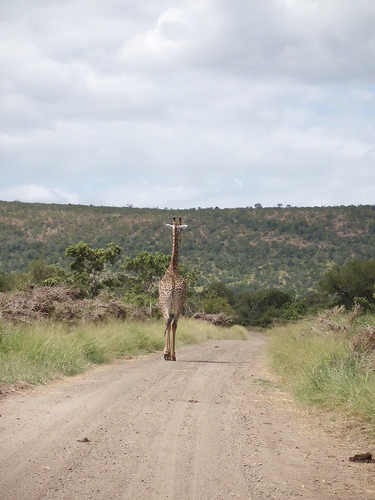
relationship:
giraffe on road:
[155, 217, 186, 361] [1, 325, 373, 496]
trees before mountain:
[0, 240, 374, 331] [1, 201, 374, 299]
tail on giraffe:
[163, 279, 176, 337] [155, 217, 186, 361]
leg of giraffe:
[170, 314, 180, 362] [155, 217, 186, 361]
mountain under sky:
[1, 201, 374, 299] [1, 1, 373, 209]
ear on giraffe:
[178, 222, 189, 230] [155, 217, 186, 361]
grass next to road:
[2, 317, 249, 397] [1, 325, 373, 496]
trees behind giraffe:
[64, 240, 121, 302] [155, 217, 186, 361]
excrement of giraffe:
[77, 434, 90, 444] [155, 217, 186, 361]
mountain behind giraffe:
[1, 201, 374, 299] [155, 217, 186, 361]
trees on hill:
[64, 240, 121, 302] [1, 279, 240, 333]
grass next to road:
[263, 305, 374, 425] [1, 325, 373, 496]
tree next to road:
[64, 240, 121, 302] [1, 325, 373, 496]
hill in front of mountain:
[1, 279, 240, 333] [1, 201, 374, 299]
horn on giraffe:
[169, 216, 179, 226] [155, 217, 186, 361]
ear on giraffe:
[163, 223, 173, 229] [155, 217, 186, 361]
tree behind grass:
[64, 240, 121, 302] [2, 317, 249, 397]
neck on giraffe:
[168, 229, 179, 269] [155, 217, 186, 361]